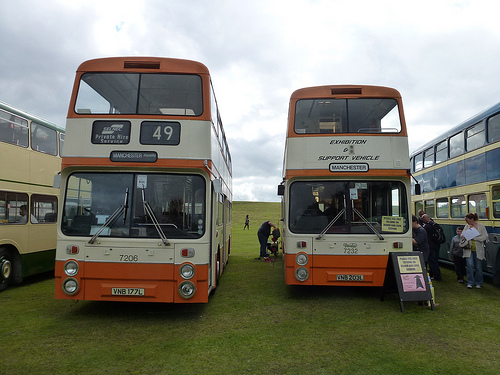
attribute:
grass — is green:
[3, 292, 498, 373]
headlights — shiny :
[177, 265, 202, 297]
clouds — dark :
[6, 7, 60, 80]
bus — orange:
[281, 75, 420, 292]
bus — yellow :
[260, 66, 442, 333]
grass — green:
[2, 207, 496, 372]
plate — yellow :
[105, 286, 150, 296]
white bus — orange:
[279, 85, 413, 288]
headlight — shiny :
[295, 252, 310, 264]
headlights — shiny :
[293, 249, 317, 284]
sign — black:
[389, 252, 421, 318]